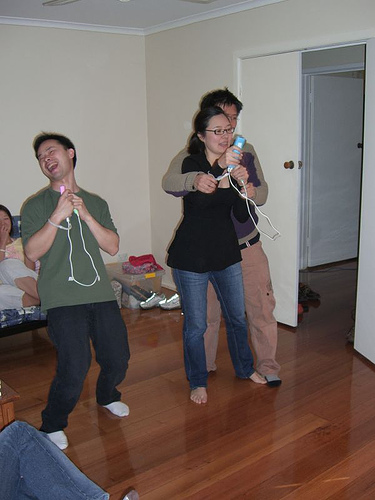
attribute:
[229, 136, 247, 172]
remote — wii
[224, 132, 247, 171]
game controller — blue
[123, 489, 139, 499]
sock — white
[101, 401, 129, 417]
sock — white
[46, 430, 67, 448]
sock — white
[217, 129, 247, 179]
controls — game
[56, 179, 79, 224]
controls — game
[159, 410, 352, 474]
wood floor — brown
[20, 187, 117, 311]
t-shirt — green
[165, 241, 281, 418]
legs — apart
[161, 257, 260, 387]
jeans — blue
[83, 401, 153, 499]
shadow — reflection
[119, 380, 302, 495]
floor — wooden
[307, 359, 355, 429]
floor — wooden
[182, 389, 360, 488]
floor — wood, polished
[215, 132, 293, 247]
game — wii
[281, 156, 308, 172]
handle — door